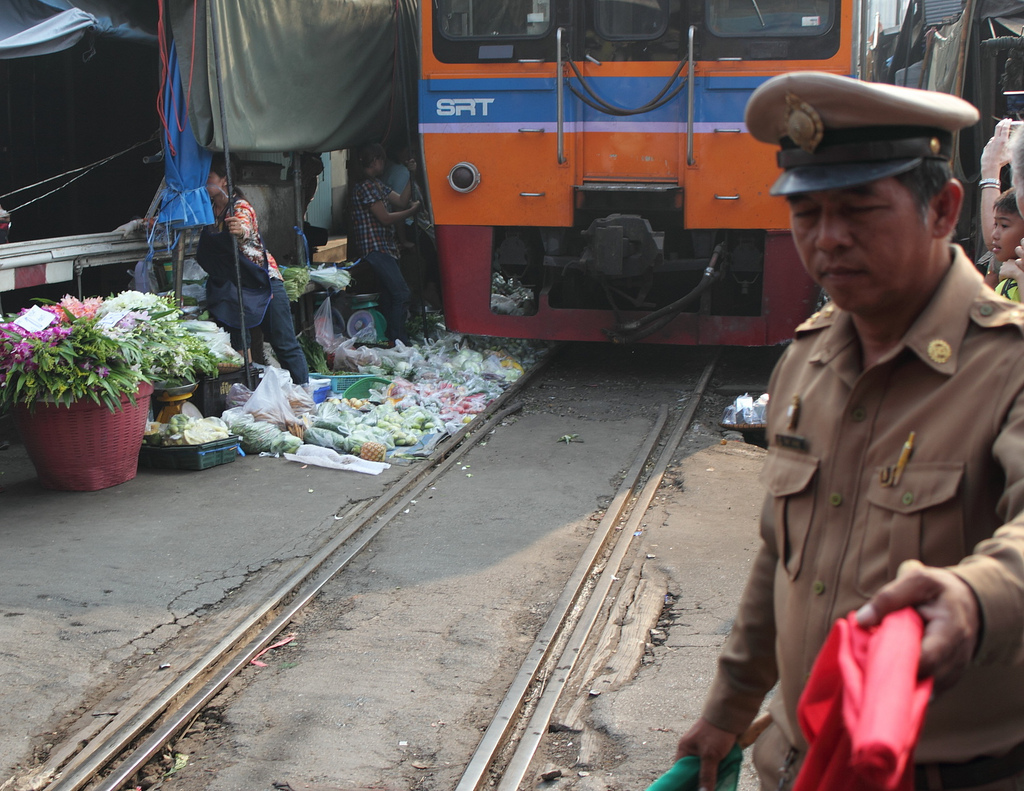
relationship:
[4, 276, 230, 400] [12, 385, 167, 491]
plant in pot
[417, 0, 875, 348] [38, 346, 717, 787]
train on tracks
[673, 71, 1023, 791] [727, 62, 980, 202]
man wears hat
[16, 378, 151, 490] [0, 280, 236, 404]
flower basket holding plant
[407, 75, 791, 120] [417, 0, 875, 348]
stripe on train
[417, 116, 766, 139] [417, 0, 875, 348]
stripe on train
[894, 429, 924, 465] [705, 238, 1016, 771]
pen in shirt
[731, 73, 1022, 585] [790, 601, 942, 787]
man holding flag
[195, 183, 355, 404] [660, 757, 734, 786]
man holding flag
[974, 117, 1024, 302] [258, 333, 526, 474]
child selling fruit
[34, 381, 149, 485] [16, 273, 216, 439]
flower basket with flowers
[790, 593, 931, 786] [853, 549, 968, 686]
flag in man's hand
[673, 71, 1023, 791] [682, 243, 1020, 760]
man in uniform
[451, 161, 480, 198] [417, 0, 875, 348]
light on train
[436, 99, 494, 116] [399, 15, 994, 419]
lettering on train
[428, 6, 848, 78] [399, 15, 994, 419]
window on front of train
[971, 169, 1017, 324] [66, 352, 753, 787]
child near tracks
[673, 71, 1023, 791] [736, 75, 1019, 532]
man wearing uniform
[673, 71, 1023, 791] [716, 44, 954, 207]
man wearing brown hat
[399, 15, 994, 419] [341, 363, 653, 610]
train on tracks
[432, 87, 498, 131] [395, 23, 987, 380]
lettering on train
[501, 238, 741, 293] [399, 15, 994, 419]
bars on train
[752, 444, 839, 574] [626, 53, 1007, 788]
pockets on uniform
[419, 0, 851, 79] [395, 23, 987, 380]
window on train